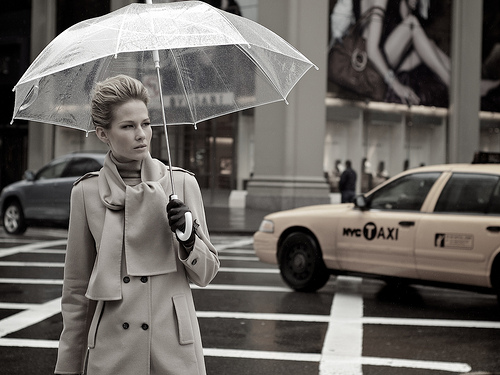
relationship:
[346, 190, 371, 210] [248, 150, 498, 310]
rearview mirror of a car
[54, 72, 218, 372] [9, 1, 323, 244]
woman holding umbrella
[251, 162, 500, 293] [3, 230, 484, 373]
car crossing over crosswalk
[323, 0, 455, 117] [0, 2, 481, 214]
picture on building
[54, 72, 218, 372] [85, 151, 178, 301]
woman wearing scarf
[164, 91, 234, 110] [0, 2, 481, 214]
writing on building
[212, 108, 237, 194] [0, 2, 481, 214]
window on building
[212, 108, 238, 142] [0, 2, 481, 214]
window on building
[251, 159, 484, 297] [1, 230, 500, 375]
car on a road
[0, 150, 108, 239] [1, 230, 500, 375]
vehicle on a road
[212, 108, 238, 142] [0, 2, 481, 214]
window on a building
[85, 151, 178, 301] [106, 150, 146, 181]
scarf around neck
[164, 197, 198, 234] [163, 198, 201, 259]
hand wearing a glove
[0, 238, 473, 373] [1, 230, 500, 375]
lines on a road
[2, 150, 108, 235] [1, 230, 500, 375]
vehicle on road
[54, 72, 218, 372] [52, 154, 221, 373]
woman wearing a coat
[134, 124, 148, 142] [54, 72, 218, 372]
nose of woman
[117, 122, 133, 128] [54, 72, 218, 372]
eye of woman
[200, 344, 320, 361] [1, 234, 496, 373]
line on road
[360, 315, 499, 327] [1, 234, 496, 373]
lines on road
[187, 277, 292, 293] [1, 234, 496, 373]
line on road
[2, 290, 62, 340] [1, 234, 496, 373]
line on road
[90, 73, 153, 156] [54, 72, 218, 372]
head of woman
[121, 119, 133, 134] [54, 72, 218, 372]
eye of woman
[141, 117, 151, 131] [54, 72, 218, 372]
eye of woman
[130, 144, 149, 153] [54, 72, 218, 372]
lips of woman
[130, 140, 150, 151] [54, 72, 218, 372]
lips of woman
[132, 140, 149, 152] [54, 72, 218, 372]
mouth of woman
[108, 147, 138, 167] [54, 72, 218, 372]
neck of woman